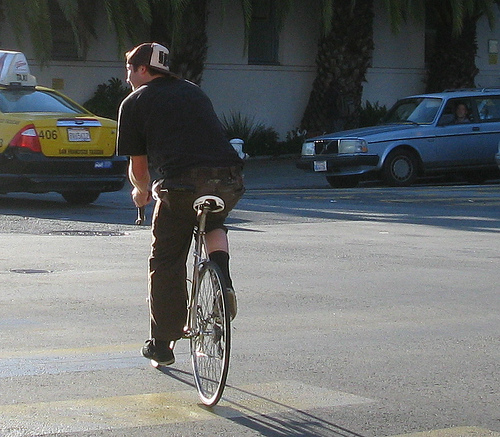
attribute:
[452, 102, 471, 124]
man — driving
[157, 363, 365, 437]
shadow — large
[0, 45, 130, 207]
taxi cab — yellow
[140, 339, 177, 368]
shoe — black, white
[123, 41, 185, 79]
baseball cap — being worn, backwards, red, white, brown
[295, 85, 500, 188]
car — blue, light blue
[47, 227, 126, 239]
manhole cover — round, metal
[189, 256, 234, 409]
back tire — large, white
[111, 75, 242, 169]
shirt — black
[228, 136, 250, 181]
fire hydrant — white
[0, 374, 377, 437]
line — white, large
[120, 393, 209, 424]
smudge — brown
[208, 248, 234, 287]
sock — black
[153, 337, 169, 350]
sock — black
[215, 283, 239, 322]
tennis shoe — black, white